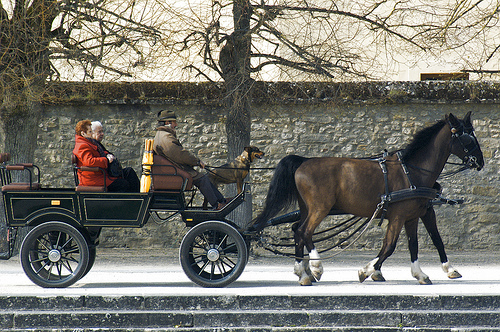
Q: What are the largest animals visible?
A: Horses.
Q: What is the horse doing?
A: Pulling a carriage.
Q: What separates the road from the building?
A: Stone wall.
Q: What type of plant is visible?
A: Trees.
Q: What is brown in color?
A: Horse.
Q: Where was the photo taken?
A: Outside somewhere.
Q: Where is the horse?
A: On the ground.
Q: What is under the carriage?
A: Wheels.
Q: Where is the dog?
A: Next to the man.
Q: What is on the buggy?
A: A dog.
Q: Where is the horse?
A: In front of the buggy.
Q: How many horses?
A: 2.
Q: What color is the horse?
A: Brown.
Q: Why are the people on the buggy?
A: Traveling.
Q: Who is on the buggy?
A: 2 men and and woman.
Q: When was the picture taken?
A: Daytime.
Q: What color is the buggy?
A: Black.